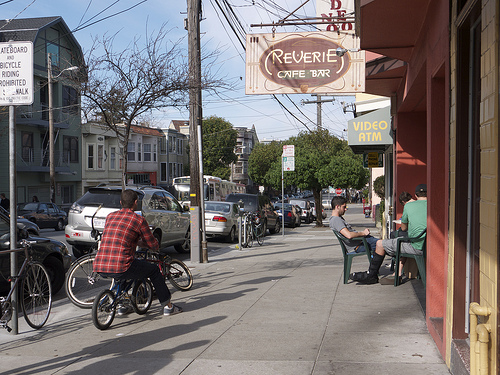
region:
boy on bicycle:
[86, 181, 195, 355]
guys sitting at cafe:
[316, 175, 436, 290]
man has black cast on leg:
[338, 242, 416, 308]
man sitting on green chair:
[325, 184, 395, 278]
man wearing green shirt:
[385, 192, 450, 252]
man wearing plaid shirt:
[85, 163, 170, 308]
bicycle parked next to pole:
[0, 220, 72, 357]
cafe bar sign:
[238, 35, 403, 88]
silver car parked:
[56, 160, 253, 270]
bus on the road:
[156, 161, 266, 220]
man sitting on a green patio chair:
[327, 186, 377, 276]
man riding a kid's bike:
[100, 185, 170, 321]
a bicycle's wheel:
[17, 232, 53, 340]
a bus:
[175, 173, 237, 198]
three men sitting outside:
[323, 185, 429, 277]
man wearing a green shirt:
[405, 200, 431, 250]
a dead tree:
[87, 31, 185, 131]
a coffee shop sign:
[240, 20, 366, 91]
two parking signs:
[276, 140, 298, 195]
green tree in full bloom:
[273, 134, 365, 195]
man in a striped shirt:
[69, 179, 174, 291]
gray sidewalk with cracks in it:
[221, 240, 317, 350]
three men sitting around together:
[302, 177, 430, 241]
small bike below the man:
[69, 272, 157, 330]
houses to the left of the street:
[59, 117, 165, 179]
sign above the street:
[264, 134, 310, 241]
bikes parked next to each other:
[6, 231, 104, 321]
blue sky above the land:
[93, 8, 140, 43]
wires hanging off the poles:
[219, 1, 251, 58]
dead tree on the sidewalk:
[82, 7, 169, 177]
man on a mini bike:
[71, 183, 186, 330]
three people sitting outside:
[324, 188, 432, 294]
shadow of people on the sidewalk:
[35, 311, 266, 369]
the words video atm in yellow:
[338, 103, 400, 154]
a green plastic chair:
[333, 220, 380, 288]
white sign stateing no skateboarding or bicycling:
[1, 22, 38, 356]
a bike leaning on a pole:
[1, 225, 53, 345]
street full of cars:
[54, 160, 332, 260]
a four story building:
[6, 7, 103, 229]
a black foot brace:
[346, 240, 387, 289]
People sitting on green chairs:
[329, 182, 426, 286]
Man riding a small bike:
[89, 187, 183, 327]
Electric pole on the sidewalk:
[187, 0, 202, 265]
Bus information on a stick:
[282, 144, 294, 171]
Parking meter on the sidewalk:
[235, 197, 244, 249]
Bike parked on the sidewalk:
[239, 211, 267, 245]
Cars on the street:
[2, 182, 338, 299]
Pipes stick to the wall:
[467, 300, 492, 373]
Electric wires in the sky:
[1, 3, 353, 145]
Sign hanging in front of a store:
[245, 28, 364, 93]